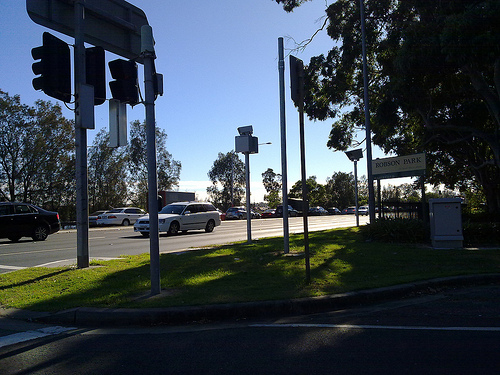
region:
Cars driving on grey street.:
[0, 185, 436, 280]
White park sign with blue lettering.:
[369, 152, 428, 244]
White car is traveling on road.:
[130, 199, 227, 236]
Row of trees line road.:
[0, 81, 492, 216]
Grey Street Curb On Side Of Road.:
[37, 262, 497, 327]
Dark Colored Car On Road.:
[0, 199, 61, 244]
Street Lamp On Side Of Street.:
[23, 38, 172, 300]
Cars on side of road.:
[0, 198, 417, 250]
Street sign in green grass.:
[287, 51, 318, 298]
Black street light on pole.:
[30, 39, 109, 274]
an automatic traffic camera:
[233, 123, 273, 243]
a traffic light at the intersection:
[31, 30, 74, 107]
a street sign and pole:
[26, 1, 165, 293]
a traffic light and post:
[31, 32, 166, 298]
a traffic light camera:
[345, 148, 365, 227]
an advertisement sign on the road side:
[371, 153, 429, 232]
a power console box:
[423, 194, 465, 253]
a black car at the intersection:
[0, 200, 62, 242]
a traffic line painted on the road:
[0, 319, 498, 372]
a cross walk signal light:
[108, 56, 143, 108]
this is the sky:
[199, 19, 241, 64]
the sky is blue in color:
[188, 10, 270, 85]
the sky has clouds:
[166, 34, 241, 76]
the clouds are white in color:
[183, 126, 208, 147]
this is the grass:
[206, 258, 247, 282]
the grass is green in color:
[47, 273, 76, 279]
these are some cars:
[1, 193, 224, 238]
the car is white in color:
[189, 215, 199, 222]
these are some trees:
[384, 11, 493, 108]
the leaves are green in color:
[389, 28, 451, 88]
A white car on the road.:
[134, 198, 224, 238]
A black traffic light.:
[30, 30, 70, 104]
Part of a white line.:
[368, 318, 424, 333]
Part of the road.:
[167, 345, 245, 368]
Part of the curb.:
[224, 295, 286, 322]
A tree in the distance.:
[261, 168, 283, 208]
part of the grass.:
[331, 252, 355, 274]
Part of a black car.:
[1, 197, 62, 242]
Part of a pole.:
[144, 181, 164, 293]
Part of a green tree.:
[374, 105, 414, 149]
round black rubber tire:
[167, 219, 182, 233]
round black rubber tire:
[205, 218, 216, 233]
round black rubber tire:
[33, 225, 50, 237]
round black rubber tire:
[120, 218, 130, 226]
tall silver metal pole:
[70, 4, 97, 267]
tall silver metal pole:
[140, 29, 172, 293]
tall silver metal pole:
[242, 152, 254, 244]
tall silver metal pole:
[275, 35, 292, 251]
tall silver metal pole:
[356, 0, 377, 227]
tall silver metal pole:
[351, 159, 362, 229]